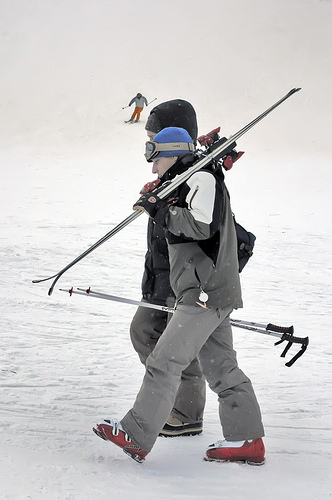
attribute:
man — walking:
[101, 131, 275, 472]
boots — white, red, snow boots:
[90, 410, 271, 472]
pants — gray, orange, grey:
[128, 302, 263, 450]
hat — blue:
[151, 125, 193, 156]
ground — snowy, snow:
[5, 3, 331, 499]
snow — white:
[3, 4, 330, 499]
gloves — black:
[133, 192, 164, 217]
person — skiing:
[121, 90, 159, 131]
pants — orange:
[129, 105, 147, 122]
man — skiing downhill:
[135, 92, 250, 445]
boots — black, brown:
[162, 410, 204, 443]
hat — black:
[148, 99, 201, 146]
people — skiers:
[93, 94, 295, 484]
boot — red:
[199, 434, 269, 470]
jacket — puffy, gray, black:
[161, 172, 246, 314]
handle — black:
[279, 330, 307, 353]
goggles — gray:
[141, 139, 198, 158]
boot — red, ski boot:
[90, 415, 152, 468]